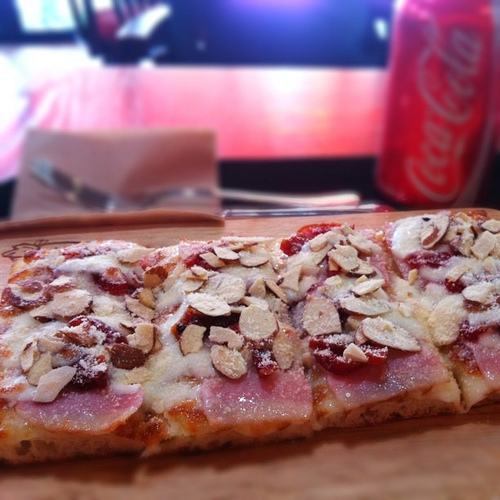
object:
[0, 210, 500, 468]
pizza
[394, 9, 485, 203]
coke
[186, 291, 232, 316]
nuts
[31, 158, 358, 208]
fork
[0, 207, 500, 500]
tray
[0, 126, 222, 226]
napkin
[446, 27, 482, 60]
letters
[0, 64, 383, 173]
table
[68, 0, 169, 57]
chair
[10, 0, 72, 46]
door